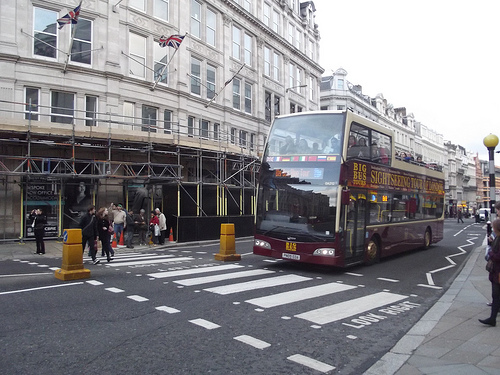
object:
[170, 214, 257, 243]
black walls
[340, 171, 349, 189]
edge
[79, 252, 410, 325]
crosswalk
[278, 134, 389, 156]
people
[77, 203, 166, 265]
people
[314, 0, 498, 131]
sky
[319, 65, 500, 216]
building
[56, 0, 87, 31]
flag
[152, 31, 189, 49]
flag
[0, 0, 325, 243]
building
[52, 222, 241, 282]
dividers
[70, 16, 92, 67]
window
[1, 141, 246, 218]
metal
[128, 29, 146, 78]
window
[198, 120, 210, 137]
window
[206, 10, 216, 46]
window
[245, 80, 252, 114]
window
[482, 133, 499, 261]
lamp post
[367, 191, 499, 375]
sidewalk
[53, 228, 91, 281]
pillar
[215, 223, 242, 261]
pillar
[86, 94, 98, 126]
window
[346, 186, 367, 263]
door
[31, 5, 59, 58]
window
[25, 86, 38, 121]
window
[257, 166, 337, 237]
windshield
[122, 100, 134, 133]
window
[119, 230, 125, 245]
cone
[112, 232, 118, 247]
cone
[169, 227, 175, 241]
cone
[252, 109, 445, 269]
bus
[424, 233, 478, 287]
zigzag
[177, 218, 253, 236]
wall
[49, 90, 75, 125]
window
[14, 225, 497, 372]
road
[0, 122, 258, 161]
awning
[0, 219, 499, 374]
street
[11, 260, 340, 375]
lines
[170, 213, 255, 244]
subway stairs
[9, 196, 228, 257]
sidewalk